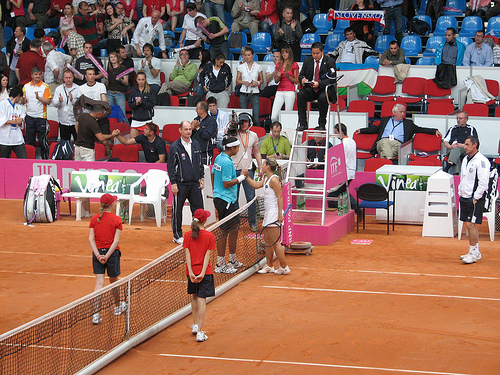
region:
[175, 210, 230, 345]
Woman in red hat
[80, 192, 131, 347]
Woman in red hat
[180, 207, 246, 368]
Woman wearing red shirt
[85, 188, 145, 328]
Woman wearing red shirt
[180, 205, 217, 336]
Woman wearing black shorts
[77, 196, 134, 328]
Woman wearing black shorts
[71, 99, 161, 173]
Two men shaking hands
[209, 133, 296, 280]
Two woman shaking hands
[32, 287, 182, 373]
Black and white netting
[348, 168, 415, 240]
Blue and black chair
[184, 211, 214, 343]
woman wearing red shirt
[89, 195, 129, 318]
woman wearing red shirt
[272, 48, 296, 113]
woman wearing red shirt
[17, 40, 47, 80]
man wearing red shirt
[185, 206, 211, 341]
woman wearing red hat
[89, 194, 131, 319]
woman wearing red hat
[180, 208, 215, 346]
woman wearing black shorts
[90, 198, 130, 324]
woman wearing black shorts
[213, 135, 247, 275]
woman wearing black shorts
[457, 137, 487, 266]
man wearing black shorts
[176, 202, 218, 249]
a woman wearing a red hat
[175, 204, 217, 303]
a woman wearing a red shirt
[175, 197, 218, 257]
a woman wearing her hair in a pony tail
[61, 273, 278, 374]
a net on a tennis court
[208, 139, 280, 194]
two woman shaking hands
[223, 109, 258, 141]
a man holding a camera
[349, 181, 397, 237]
a blue and black chair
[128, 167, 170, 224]
a white plastic lawn chair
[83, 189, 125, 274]
a woman standing with her hands behind her back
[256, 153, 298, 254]
a woman holding a tennis racket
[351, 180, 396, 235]
Blue chair facing the crowd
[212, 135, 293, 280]
competitors shake hands over the net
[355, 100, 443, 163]
Man relaxes in chair after the game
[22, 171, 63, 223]
Black and white bag on the sidelines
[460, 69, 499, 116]
Clothing draped over a chair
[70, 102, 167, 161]
Men shake hands at event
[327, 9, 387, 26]
Banner in the spectator section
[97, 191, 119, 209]
Red cap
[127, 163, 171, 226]
White, plastic chair on the sidelines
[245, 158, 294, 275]
Competitor holds a tennis racket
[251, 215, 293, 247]
Tennis racket in the player's hand.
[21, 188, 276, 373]
The net frame is white.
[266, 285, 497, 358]
The court is brown.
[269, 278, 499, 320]
White line on the court.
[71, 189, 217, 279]
Girls are wearing red shirts.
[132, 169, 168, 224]
White chair on the sideline.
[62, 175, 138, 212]
Bench on the sideline.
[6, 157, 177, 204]
The wall is pink.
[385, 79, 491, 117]
The chairs are red.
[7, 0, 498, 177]
Spectators in the stand.